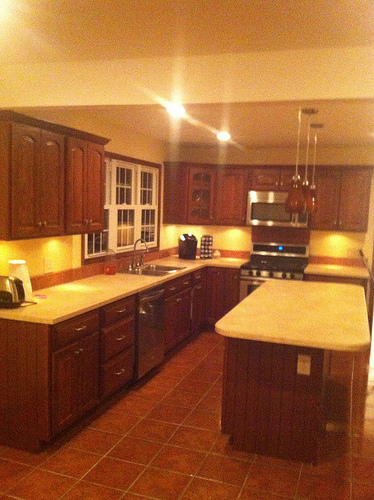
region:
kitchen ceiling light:
[170, 93, 202, 125]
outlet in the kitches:
[288, 348, 315, 378]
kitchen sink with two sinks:
[127, 236, 185, 279]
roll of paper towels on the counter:
[12, 252, 42, 309]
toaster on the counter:
[0, 276, 30, 306]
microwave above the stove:
[236, 194, 314, 230]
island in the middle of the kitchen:
[214, 262, 367, 459]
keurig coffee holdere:
[199, 230, 215, 262]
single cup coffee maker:
[174, 232, 200, 262]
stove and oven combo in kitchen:
[234, 234, 308, 281]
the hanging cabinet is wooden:
[5, 99, 194, 327]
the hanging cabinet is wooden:
[11, 120, 133, 242]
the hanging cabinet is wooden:
[57, 156, 358, 270]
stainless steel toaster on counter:
[0, 274, 26, 305]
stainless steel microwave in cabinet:
[246, 192, 312, 226]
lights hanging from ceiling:
[281, 106, 323, 216]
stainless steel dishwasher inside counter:
[135, 289, 168, 378]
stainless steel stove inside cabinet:
[241, 244, 310, 327]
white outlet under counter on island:
[295, 351, 307, 371]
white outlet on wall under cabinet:
[40, 254, 46, 267]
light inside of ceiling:
[160, 99, 185, 126]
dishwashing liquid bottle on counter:
[103, 247, 116, 274]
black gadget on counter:
[179, 231, 197, 257]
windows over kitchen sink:
[75, 145, 163, 262]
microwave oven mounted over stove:
[242, 183, 314, 234]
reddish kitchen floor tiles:
[0, 318, 368, 498]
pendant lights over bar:
[283, 103, 328, 223]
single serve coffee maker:
[171, 229, 198, 263]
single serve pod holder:
[197, 231, 216, 261]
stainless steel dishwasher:
[131, 282, 168, 387]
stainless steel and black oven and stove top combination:
[235, 240, 312, 304]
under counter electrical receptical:
[293, 350, 316, 378]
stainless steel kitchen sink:
[117, 256, 189, 278]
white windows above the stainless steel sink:
[83, 150, 186, 278]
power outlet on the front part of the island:
[216, 323, 369, 464]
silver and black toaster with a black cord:
[2, 274, 35, 308]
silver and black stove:
[240, 242, 311, 302]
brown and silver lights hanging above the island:
[213, 161, 371, 465]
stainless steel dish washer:
[136, 286, 167, 381]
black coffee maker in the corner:
[178, 232, 197, 258]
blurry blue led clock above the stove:
[240, 241, 309, 280]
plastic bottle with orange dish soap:
[103, 248, 117, 275]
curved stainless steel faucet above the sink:
[119, 238, 184, 277]